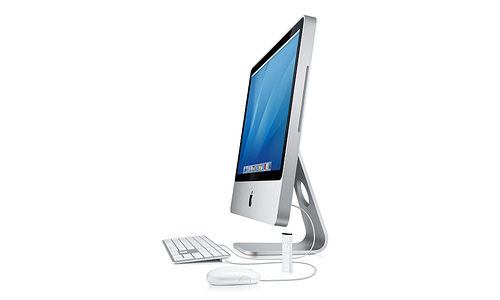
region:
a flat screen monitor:
[227, 14, 331, 222]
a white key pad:
[169, 222, 219, 277]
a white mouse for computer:
[197, 265, 265, 290]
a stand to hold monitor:
[246, 156, 337, 260]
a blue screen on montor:
[233, 49, 292, 181]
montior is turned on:
[234, 34, 296, 196]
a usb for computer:
[282, 230, 292, 274]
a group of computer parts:
[158, 14, 342, 287]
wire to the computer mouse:
[281, 254, 328, 294]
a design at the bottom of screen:
[246, 194, 256, 208]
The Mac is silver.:
[157, 11, 329, 286]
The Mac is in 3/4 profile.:
[158, 13, 332, 288]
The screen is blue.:
[231, 33, 300, 180]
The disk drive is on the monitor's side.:
[293, 61, 315, 133]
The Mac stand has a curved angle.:
[233, 159, 333, 258]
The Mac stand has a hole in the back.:
[293, 175, 318, 207]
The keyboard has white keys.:
[161, 233, 232, 264]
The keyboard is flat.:
[161, 234, 232, 265]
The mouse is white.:
[204, 263, 262, 293]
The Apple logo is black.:
[244, 187, 256, 211]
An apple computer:
[142, 9, 338, 299]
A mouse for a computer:
[207, 262, 262, 292]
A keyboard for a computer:
[162, 232, 225, 262]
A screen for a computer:
[228, 12, 318, 224]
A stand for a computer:
[287, 138, 342, 273]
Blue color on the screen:
[235, 25, 295, 167]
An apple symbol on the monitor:
[241, 189, 258, 209]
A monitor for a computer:
[227, 26, 313, 230]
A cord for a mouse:
[216, 247, 318, 281]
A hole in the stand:
[295, 178, 310, 205]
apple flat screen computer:
[129, 15, 377, 292]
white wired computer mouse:
[203, 256, 310, 288]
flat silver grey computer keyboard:
[148, 229, 233, 263]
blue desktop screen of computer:
[242, 68, 282, 153]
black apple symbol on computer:
[239, 188, 267, 208]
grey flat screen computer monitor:
[219, 20, 323, 230]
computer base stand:
[296, 171, 338, 256]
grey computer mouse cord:
[277, 270, 309, 287]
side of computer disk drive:
[293, 55, 320, 142]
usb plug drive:
[269, 217, 306, 279]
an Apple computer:
[132, 5, 343, 296]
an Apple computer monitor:
[226, 6, 326, 232]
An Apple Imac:
[155, 11, 352, 296]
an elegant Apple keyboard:
[151, 227, 233, 267]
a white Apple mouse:
[195, 265, 260, 295]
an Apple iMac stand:
[235, 161, 330, 268]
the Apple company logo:
[243, 188, 255, 210]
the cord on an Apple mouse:
[257, 257, 324, 286]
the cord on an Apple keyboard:
[216, 228, 329, 260]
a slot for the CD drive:
[296, 62, 311, 142]